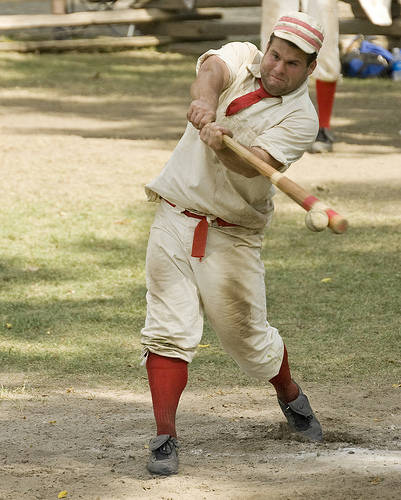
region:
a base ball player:
[141, 6, 348, 474]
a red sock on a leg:
[145, 351, 189, 431]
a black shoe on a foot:
[148, 433, 184, 476]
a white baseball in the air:
[303, 206, 329, 234]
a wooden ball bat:
[219, 126, 355, 240]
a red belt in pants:
[151, 190, 252, 258]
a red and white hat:
[270, 5, 326, 51]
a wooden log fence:
[10, 0, 189, 54]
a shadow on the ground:
[2, 212, 148, 383]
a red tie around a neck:
[221, 72, 286, 114]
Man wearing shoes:
[143, 371, 328, 482]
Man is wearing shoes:
[139, 372, 326, 481]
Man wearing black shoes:
[139, 375, 323, 477]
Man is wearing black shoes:
[142, 373, 323, 476]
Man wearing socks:
[141, 336, 303, 439]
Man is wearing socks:
[139, 333, 302, 442]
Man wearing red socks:
[142, 334, 303, 439]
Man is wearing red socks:
[143, 341, 301, 436]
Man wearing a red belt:
[157, 187, 269, 262]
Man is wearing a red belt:
[156, 186, 269, 259]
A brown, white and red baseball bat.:
[219, 134, 350, 233]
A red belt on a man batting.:
[158, 195, 239, 259]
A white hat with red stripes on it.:
[270, 10, 326, 56]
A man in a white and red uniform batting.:
[142, 13, 327, 477]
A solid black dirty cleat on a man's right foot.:
[147, 431, 181, 474]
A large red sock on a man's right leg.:
[141, 350, 189, 439]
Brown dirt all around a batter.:
[4, 374, 399, 498]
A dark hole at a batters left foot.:
[269, 427, 360, 445]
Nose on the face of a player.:
[271, 57, 286, 76]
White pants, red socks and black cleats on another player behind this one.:
[259, 1, 341, 151]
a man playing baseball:
[52, 15, 395, 272]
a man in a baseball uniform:
[115, 4, 395, 387]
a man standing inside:
[110, 15, 397, 459]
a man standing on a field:
[124, 140, 397, 494]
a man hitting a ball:
[168, 109, 397, 272]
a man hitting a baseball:
[150, 46, 390, 284]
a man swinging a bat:
[191, 52, 395, 316]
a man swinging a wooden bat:
[170, 68, 392, 312]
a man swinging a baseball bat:
[152, 51, 374, 278]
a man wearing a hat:
[163, 4, 397, 214]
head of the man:
[235, 12, 342, 104]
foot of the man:
[129, 422, 198, 483]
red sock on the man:
[128, 355, 206, 424]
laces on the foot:
[146, 433, 187, 459]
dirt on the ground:
[199, 414, 258, 475]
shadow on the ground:
[41, 374, 131, 440]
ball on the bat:
[288, 201, 337, 239]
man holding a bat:
[177, 103, 376, 244]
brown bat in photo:
[197, 109, 358, 235]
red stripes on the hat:
[260, 8, 336, 45]